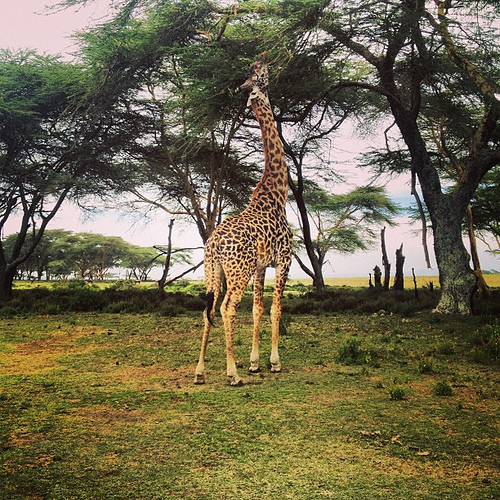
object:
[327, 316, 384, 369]
grass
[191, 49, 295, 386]
giraffe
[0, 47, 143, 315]
tree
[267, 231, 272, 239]
spot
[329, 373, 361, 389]
patches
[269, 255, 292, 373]
limbs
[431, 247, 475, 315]
moss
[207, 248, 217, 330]
tail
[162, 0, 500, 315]
trees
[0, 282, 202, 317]
bushes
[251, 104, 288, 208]
neck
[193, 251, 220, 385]
legs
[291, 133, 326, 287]
trunks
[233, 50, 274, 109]
head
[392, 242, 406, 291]
stump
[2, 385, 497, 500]
ground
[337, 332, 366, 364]
weeds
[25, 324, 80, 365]
dirt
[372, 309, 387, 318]
fungus